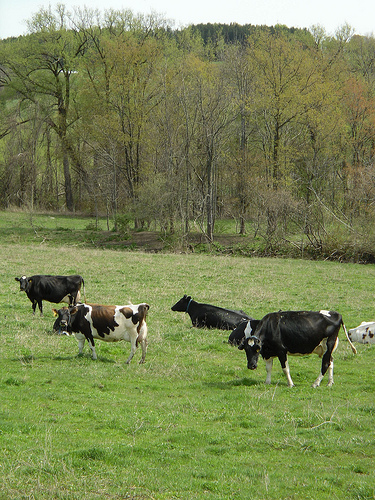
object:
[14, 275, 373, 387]
cows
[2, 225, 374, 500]
field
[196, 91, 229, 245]
tree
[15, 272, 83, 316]
cow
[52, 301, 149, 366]
cow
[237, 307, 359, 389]
cow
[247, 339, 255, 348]
spot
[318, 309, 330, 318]
spot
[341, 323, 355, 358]
tail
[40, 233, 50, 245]
stick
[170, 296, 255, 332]
cow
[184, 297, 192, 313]
collar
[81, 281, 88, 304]
tail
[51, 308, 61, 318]
ear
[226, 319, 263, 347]
cow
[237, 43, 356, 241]
tree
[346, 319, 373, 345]
cow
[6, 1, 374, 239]
trees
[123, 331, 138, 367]
leg